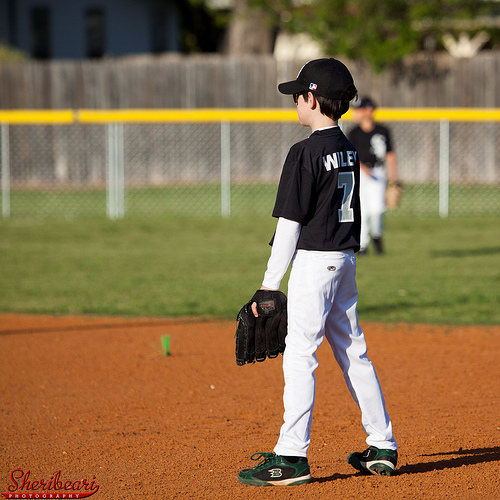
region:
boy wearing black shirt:
[233, 34, 420, 487]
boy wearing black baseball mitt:
[187, 37, 414, 466]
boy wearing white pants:
[197, 43, 414, 465]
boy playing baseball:
[193, 48, 425, 477]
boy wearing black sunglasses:
[165, 13, 407, 469]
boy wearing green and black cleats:
[182, 34, 410, 495]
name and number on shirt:
[279, 128, 377, 240]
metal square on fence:
[11, 118, 36, 148]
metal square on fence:
[40, 123, 65, 145]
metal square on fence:
[69, 128, 89, 152]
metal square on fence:
[10, 169, 30, 194]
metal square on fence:
[128, 127, 159, 152]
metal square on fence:
[195, 121, 218, 151]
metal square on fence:
[237, 123, 257, 163]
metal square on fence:
[410, 124, 441, 166]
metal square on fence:
[455, 132, 475, 163]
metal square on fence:
[450, 185, 475, 215]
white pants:
[290, 314, 310, 355]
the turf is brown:
[127, 387, 189, 442]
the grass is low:
[116, 234, 188, 282]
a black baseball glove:
[239, 310, 281, 357]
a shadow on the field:
[428, 443, 468, 468]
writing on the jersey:
[317, 147, 365, 226]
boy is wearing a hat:
[313, 60, 348, 83]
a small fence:
[141, 133, 210, 207]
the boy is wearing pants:
[290, 303, 323, 349]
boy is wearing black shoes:
[247, 460, 311, 487]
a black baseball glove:
[236, 290, 286, 365]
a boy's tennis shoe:
[235, 455, 315, 485]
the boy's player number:
[330, 170, 355, 225]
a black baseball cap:
[271, 55, 356, 95]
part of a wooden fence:
[0, 50, 495, 180]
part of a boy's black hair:
[315, 95, 345, 120]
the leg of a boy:
[326, 256, 396, 446]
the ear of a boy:
[302, 91, 317, 108]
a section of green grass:
[357, 222, 497, 322]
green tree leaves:
[276, 5, 456, 80]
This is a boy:
[243, 42, 405, 489]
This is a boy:
[347, 83, 404, 283]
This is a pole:
[96, 110, 134, 237]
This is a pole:
[216, 112, 241, 232]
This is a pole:
[428, 113, 458, 238]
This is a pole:
[0, 115, 24, 237]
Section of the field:
[115, 363, 232, 497]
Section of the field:
[7, 375, 217, 477]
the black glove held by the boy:
[232, 287, 287, 363]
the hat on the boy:
[278, 57, 358, 99]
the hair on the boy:
[299, 82, 359, 122]